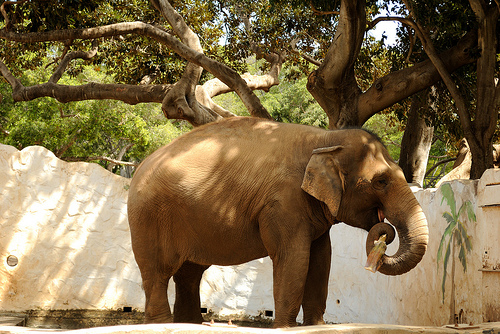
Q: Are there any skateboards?
A: No, there are no skateboards.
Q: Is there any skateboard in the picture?
A: No, there are no skateboards.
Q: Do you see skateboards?
A: No, there are no skateboards.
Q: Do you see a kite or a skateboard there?
A: No, there are no skateboards or kites.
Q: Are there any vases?
A: No, there are no vases.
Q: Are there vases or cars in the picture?
A: No, there are no vases or cars.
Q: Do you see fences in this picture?
A: No, there are no fences.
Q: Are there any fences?
A: No, there are no fences.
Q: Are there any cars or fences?
A: No, there are no fences or cars.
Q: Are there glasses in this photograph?
A: No, there are no glasses.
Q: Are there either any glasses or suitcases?
A: No, there are no glasses or suitcases.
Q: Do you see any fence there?
A: No, there are no fences.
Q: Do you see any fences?
A: No, there are no fences.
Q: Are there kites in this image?
A: No, there are no kites.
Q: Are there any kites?
A: No, there are no kites.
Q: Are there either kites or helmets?
A: No, there are no kites or helmets.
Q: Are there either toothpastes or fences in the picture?
A: No, there are no fences or toothpastes.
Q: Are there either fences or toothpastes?
A: No, there are no fences or toothpastes.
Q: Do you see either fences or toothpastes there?
A: No, there are no fences or toothpastes.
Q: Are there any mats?
A: No, there are no mats.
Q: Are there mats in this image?
A: No, there are no mats.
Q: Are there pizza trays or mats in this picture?
A: No, there are no mats or pizza trays.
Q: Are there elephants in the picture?
A: Yes, there is an elephant.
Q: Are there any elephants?
A: Yes, there is an elephant.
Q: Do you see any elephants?
A: Yes, there is an elephant.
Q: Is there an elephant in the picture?
A: Yes, there is an elephant.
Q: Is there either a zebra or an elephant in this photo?
A: Yes, there is an elephant.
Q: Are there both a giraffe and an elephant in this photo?
A: No, there is an elephant but no giraffes.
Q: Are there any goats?
A: No, there are no goats.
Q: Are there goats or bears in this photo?
A: No, there are no goats or bears.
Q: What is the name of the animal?
A: The animal is an elephant.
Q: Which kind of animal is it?
A: The animal is an elephant.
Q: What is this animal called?
A: This is an elephant.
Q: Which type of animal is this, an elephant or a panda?
A: This is an elephant.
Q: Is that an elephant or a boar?
A: That is an elephant.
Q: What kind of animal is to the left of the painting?
A: The animal is an elephant.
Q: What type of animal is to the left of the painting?
A: The animal is an elephant.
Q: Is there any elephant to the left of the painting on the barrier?
A: Yes, there is an elephant to the left of the painting.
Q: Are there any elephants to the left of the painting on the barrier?
A: Yes, there is an elephant to the left of the painting.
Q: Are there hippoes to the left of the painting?
A: No, there is an elephant to the left of the painting.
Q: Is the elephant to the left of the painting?
A: Yes, the elephant is to the left of the painting.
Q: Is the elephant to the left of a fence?
A: No, the elephant is to the left of the painting.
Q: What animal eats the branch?
A: The elephant eats the branch.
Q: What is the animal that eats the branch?
A: The animal is an elephant.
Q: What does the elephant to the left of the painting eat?
A: The elephant eats a branch.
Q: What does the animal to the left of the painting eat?
A: The elephant eats a branch.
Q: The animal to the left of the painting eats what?
A: The elephant eats a branch.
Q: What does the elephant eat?
A: The elephant eats a branch.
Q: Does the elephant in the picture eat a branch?
A: Yes, the elephant eats a branch.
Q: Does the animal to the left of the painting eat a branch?
A: Yes, the elephant eats a branch.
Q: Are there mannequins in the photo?
A: No, there are no mannequins.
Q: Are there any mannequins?
A: No, there are no mannequins.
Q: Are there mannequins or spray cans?
A: No, there are no mannequins or spray cans.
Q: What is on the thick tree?
A: The leaves are on the tree.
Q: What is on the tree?
A: The leaves are on the tree.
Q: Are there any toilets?
A: No, there are no toilets.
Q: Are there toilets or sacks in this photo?
A: No, there are no toilets or sacks.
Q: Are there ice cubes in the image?
A: No, there are no ice cubes.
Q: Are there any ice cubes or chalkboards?
A: No, there are no ice cubes or chalkboards.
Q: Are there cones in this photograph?
A: No, there are no cones.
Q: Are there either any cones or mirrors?
A: No, there are no cones or mirrors.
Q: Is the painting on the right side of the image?
A: Yes, the painting is on the right of the image.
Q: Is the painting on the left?
A: No, the painting is on the right of the image.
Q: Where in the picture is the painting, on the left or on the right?
A: The painting is on the right of the image.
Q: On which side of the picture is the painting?
A: The painting is on the right of the image.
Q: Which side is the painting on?
A: The painting is on the right of the image.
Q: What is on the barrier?
A: The painting is on the barrier.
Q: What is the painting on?
A: The painting is on the barrier.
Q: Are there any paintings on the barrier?
A: Yes, there is a painting on the barrier.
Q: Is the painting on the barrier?
A: Yes, the painting is on the barrier.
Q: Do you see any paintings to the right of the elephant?
A: Yes, there is a painting to the right of the elephant.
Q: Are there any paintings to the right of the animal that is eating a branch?
A: Yes, there is a painting to the right of the elephant.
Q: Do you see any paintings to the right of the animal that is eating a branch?
A: Yes, there is a painting to the right of the elephant.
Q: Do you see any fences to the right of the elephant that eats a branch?
A: No, there is a painting to the right of the elephant.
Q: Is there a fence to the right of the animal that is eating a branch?
A: No, there is a painting to the right of the elephant.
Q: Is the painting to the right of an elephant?
A: Yes, the painting is to the right of an elephant.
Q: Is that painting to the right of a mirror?
A: No, the painting is to the right of an elephant.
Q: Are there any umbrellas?
A: No, there are no umbrellas.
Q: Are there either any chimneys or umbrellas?
A: No, there are no umbrellas or chimneys.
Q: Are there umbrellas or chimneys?
A: No, there are no umbrellas or chimneys.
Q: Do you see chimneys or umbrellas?
A: No, there are no umbrellas or chimneys.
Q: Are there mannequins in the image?
A: No, there are no mannequins.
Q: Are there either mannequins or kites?
A: No, there are no mannequins or kites.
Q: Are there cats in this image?
A: No, there are no cats.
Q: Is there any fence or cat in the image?
A: No, there are no cats or fences.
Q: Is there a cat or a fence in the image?
A: No, there are no cats or fences.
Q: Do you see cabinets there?
A: No, there are no cabinets.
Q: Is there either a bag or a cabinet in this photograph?
A: No, there are no cabinets or bags.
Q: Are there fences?
A: No, there are no fences.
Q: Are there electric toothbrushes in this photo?
A: No, there are no electric toothbrushes.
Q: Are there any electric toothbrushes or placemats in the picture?
A: No, there are no electric toothbrushes or placemats.